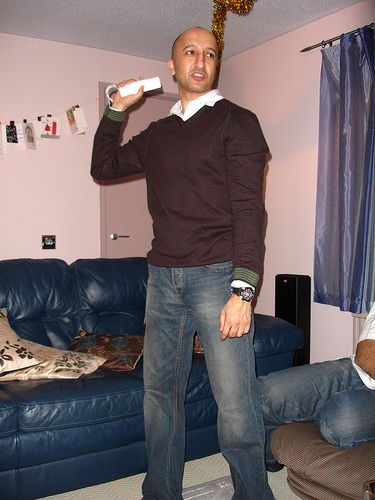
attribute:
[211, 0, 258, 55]
christmas tinsel — gold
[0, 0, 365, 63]
ceiling — white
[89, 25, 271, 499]
man — bald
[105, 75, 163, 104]
wii controller — white, wireless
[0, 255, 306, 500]
couch — black, leather, blue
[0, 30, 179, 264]
wall — pale pink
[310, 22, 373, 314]
curtains — blue, sheer, purple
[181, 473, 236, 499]
rug — grey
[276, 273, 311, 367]
speaker — large, black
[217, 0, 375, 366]
wall — pale pink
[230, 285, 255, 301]
watch — black, large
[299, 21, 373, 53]
rod — narrow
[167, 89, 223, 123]
shirt — white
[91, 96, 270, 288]
shirt — dark, brown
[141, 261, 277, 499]
jeans — blue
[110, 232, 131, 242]
handle — metal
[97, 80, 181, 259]
door — entry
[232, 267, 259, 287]
cuff — green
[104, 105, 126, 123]
cuff — green